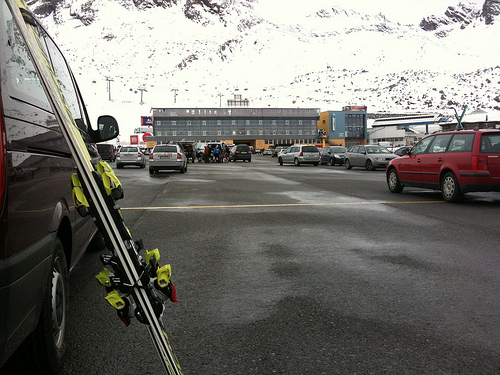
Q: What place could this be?
A: It is a pavement.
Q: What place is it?
A: It is a pavement.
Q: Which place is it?
A: It is a pavement.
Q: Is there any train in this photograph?
A: No, there are no trains.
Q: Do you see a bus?
A: No, there are no buses.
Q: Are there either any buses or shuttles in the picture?
A: No, there are no buses or shuttles.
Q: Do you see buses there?
A: No, there are no buses.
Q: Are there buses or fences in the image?
A: No, there are no buses or fences.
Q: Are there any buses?
A: No, there are no buses.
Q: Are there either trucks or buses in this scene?
A: No, there are no buses or trucks.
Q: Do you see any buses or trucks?
A: No, there are no buses or trucks.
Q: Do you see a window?
A: Yes, there is a window.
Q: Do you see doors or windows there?
A: Yes, there is a window.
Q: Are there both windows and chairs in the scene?
A: No, there is a window but no chairs.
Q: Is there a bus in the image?
A: No, there are no buses.